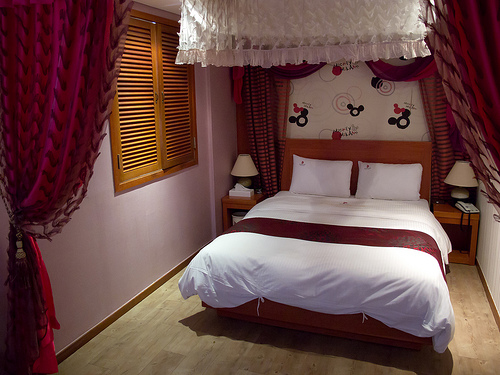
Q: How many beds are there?
A: One.